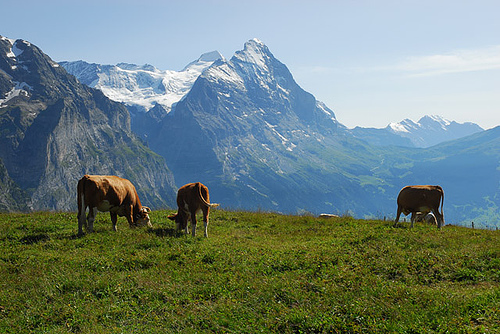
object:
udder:
[97, 200, 112, 212]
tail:
[195, 182, 219, 208]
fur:
[101, 182, 115, 191]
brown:
[117, 179, 124, 183]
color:
[120, 189, 134, 197]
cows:
[409, 214, 438, 226]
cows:
[167, 182, 220, 238]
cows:
[77, 174, 152, 235]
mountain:
[348, 115, 485, 149]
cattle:
[394, 185, 445, 228]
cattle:
[167, 182, 219, 238]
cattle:
[77, 174, 153, 238]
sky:
[51, 10, 500, 32]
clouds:
[437, 73, 500, 103]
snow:
[125, 91, 146, 104]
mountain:
[54, 50, 231, 148]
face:
[134, 206, 153, 229]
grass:
[87, 301, 392, 334]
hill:
[0, 33, 179, 214]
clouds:
[0, 1, 116, 30]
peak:
[154, 37, 500, 232]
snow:
[155, 70, 190, 86]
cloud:
[395, 96, 431, 115]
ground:
[0, 208, 500, 334]